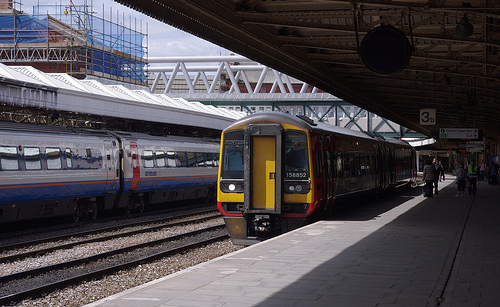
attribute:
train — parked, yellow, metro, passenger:
[213, 114, 418, 246]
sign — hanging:
[416, 105, 438, 128]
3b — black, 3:
[420, 111, 435, 127]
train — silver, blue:
[1, 121, 226, 222]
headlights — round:
[285, 184, 308, 196]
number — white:
[281, 168, 313, 183]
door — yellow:
[244, 133, 279, 215]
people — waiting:
[418, 152, 500, 204]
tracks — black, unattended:
[2, 198, 230, 304]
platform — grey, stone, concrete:
[86, 180, 496, 305]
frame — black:
[244, 121, 284, 217]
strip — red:
[0, 171, 217, 188]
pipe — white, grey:
[120, 51, 342, 106]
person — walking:
[454, 160, 469, 194]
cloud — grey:
[18, 1, 233, 63]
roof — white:
[1, 61, 246, 132]